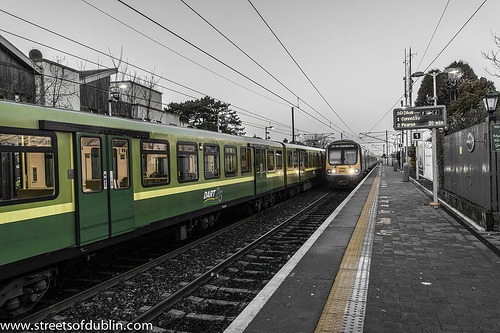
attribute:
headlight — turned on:
[346, 167, 355, 176]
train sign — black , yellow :
[373, 90, 458, 142]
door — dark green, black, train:
[83, 130, 114, 245]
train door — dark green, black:
[73, 129, 113, 244]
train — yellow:
[261, 108, 393, 228]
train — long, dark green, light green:
[11, 84, 328, 262]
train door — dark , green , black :
[251, 145, 258, 195]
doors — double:
[72, 126, 138, 248]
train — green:
[0, 95, 325, 317]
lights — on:
[7, 135, 293, 200]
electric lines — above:
[3, 2, 498, 78]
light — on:
[325, 165, 362, 178]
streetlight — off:
[476, 85, 498, 116]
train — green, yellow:
[316, 138, 378, 189]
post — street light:
[411, 63, 468, 208]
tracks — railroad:
[3, 182, 317, 327]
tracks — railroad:
[126, 180, 363, 327]